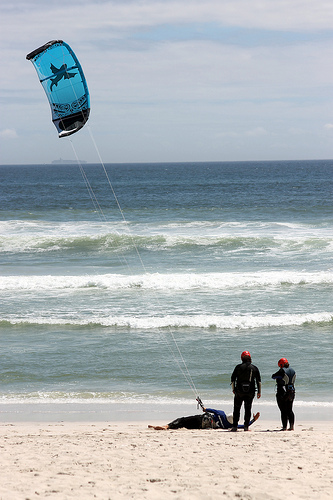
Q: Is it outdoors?
A: Yes, it is outdoors.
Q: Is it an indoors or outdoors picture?
A: It is outdoors.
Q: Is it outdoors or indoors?
A: It is outdoors.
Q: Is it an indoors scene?
A: No, it is outdoors.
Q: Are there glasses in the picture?
A: No, there are no glasses.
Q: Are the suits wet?
A: Yes, the suits are wet.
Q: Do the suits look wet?
A: Yes, the suits are wet.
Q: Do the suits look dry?
A: No, the suits are wet.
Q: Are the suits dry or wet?
A: The suits are wet.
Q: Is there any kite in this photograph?
A: Yes, there is a kite.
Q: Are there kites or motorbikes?
A: Yes, there is a kite.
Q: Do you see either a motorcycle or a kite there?
A: Yes, there is a kite.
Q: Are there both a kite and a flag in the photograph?
A: No, there is a kite but no flags.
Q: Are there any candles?
A: No, there are no candles.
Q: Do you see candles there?
A: No, there are no candles.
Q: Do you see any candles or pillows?
A: No, there are no candles or pillows.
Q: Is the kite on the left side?
A: Yes, the kite is on the left of the image.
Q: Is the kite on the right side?
A: No, the kite is on the left of the image.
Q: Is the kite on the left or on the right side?
A: The kite is on the left of the image.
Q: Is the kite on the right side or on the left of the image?
A: The kite is on the left of the image.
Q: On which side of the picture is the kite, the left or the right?
A: The kite is on the left of the image.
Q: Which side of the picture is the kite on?
A: The kite is on the left of the image.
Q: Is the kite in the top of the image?
A: Yes, the kite is in the top of the image.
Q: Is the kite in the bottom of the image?
A: No, the kite is in the top of the image.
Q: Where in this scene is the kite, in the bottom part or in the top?
A: The kite is in the top of the image.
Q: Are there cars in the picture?
A: No, there are no cars.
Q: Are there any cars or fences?
A: No, there are no cars or fences.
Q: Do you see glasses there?
A: No, there are no glasses.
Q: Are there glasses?
A: No, there are no glasses.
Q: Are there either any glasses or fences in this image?
A: No, there are no glasses or fences.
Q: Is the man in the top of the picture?
A: No, the man is in the bottom of the image.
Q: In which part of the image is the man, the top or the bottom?
A: The man is in the bottom of the image.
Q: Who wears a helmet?
A: The man wears a helmet.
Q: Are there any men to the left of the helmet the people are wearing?
A: Yes, there is a man to the left of the helmet.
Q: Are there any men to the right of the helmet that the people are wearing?
A: No, the man is to the left of the helmet.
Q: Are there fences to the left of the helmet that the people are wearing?
A: No, there is a man to the left of the helmet.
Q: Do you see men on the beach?
A: Yes, there is a man on the beach.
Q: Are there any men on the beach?
A: Yes, there is a man on the beach.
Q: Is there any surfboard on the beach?
A: No, there is a man on the beach.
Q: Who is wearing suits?
A: The man is wearing suits.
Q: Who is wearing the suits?
A: The man is wearing suits.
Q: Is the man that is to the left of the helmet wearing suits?
A: Yes, the man is wearing suits.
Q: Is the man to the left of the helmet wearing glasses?
A: No, the man is wearing suits.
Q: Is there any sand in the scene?
A: Yes, there is sand.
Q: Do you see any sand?
A: Yes, there is sand.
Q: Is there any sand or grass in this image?
A: Yes, there is sand.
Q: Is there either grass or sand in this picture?
A: Yes, there is sand.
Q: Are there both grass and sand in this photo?
A: No, there is sand but no grass.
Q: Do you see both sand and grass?
A: No, there is sand but no grass.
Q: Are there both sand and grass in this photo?
A: No, there is sand but no grass.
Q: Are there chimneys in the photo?
A: No, there are no chimneys.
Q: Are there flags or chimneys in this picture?
A: No, there are no chimneys or flags.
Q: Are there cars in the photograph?
A: No, there are no cars.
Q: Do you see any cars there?
A: No, there are no cars.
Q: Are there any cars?
A: No, there are no cars.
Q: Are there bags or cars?
A: No, there are no cars or bags.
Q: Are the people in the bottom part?
A: Yes, the people are in the bottom of the image.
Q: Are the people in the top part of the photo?
A: No, the people are in the bottom of the image.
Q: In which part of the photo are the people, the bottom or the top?
A: The people are in the bottom of the image.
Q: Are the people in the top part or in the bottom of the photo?
A: The people are in the bottom of the image.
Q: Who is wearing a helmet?
A: The people are wearing a helmet.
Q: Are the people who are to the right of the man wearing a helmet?
A: Yes, the people are wearing a helmet.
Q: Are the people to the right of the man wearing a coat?
A: No, the people are wearing a helmet.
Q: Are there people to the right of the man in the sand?
A: Yes, there are people to the right of the man.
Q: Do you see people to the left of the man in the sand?
A: No, the people are to the right of the man.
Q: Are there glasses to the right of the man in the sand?
A: No, there are people to the right of the man.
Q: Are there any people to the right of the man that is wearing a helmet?
A: Yes, there are people to the right of the man.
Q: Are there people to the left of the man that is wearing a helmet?
A: No, the people are to the right of the man.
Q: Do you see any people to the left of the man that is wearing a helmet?
A: No, the people are to the right of the man.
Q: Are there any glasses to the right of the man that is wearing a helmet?
A: No, there are people to the right of the man.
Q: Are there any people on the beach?
A: Yes, there are people on the beach.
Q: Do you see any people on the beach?
A: Yes, there are people on the beach.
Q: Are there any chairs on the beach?
A: No, there are people on the beach.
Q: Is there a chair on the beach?
A: No, there are people on the beach.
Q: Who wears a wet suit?
A: The people wear a wet suit.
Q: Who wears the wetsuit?
A: The people wear a wet suit.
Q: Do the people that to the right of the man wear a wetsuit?
A: Yes, the people wear a wetsuit.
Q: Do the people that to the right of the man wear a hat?
A: No, the people wear a wetsuit.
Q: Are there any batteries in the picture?
A: No, there are no batteries.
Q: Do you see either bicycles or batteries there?
A: No, there are no batteries or bicycles.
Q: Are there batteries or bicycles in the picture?
A: No, there are no batteries or bicycles.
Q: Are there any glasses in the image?
A: No, there are no glasses.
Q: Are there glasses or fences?
A: No, there are no glasses or fences.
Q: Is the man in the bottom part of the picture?
A: Yes, the man is in the bottom of the image.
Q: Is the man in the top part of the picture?
A: No, the man is in the bottom of the image.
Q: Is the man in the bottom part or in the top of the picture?
A: The man is in the bottom of the image.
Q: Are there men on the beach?
A: Yes, there is a man on the beach.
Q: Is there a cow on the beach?
A: No, there is a man on the beach.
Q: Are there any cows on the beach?
A: No, there is a man on the beach.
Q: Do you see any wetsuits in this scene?
A: Yes, there is a wetsuit.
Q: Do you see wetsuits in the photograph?
A: Yes, there is a wetsuit.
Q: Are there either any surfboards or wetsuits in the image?
A: Yes, there is a wetsuit.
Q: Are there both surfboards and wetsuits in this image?
A: No, there is a wetsuit but no surfboards.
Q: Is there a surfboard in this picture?
A: No, there are no surfboards.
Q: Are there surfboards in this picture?
A: No, there are no surfboards.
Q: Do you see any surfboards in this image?
A: No, there are no surfboards.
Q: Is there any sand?
A: Yes, there is sand.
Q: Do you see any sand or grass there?
A: Yes, there is sand.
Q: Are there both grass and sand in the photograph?
A: No, there is sand but no grass.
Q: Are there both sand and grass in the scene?
A: No, there is sand but no grass.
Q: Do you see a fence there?
A: No, there are no fences.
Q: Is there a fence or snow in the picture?
A: No, there are no fences or snow.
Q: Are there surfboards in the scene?
A: No, there are no surfboards.